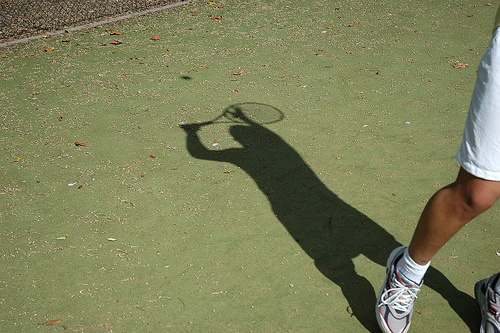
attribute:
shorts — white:
[454, 24, 498, 185]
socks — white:
[399, 257, 426, 282]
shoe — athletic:
[377, 246, 422, 332]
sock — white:
[396, 248, 431, 284]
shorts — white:
[466, 37, 496, 182]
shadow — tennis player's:
[174, 90, 486, 332]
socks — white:
[396, 240, 498, 295]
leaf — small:
[71, 135, 90, 150]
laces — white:
[383, 264, 422, 319]